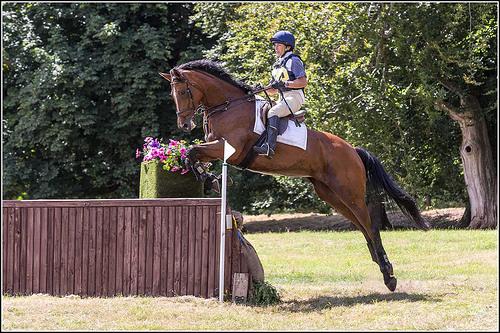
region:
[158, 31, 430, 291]
An equestrian jumping over an obstacle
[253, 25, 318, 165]
An equestrian on horseback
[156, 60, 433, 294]
A horse jumping over a wooden wall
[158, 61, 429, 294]
A horse jumping over an obstacle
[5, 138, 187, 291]
Flowers on a wooden fence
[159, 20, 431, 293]
Horseback rider jumping a wall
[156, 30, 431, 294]
A horse jumping over a wall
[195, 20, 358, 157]
Horseback rider on a horse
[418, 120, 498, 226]
A tree trunk with a hole in it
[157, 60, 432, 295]
Horse and rider obstacle course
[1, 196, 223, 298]
brown wood barrier fence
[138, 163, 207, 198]
green basket for flowers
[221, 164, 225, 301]
white metal mini flag pole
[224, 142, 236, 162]
white triangle mini flag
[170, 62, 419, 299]
brown and black horse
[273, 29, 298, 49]
blue plastic riding helmet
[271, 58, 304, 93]
blue and yellow shirt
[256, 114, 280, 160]
black leather riding boots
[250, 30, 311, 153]
woman riding on horse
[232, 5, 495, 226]
tree with green leaves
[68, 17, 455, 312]
A horses is jumping over something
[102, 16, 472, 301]
Someone is riding a horse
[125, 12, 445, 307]
A horse is moving quickly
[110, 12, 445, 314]
Someone is training their horse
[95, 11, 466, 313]
The horse is wearing a saddle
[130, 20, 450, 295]
A person is wearing a helmet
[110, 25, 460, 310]
A horse is jumping very high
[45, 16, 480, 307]
A horses is jumping on somebody's property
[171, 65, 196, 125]
The head of a horse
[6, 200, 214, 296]
A wooden fence on somebody's property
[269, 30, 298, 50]
A blue helmet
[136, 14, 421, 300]
An equestrian rider in competition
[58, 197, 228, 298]
A wooden equestrian fence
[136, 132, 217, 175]
Colorful flowers in a green planter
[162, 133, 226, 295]
A horse's front hoofs over the barrier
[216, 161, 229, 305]
A white fence pole support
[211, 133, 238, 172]
A white flag topping the pole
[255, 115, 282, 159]
Black riding boots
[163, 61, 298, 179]
A brown horse with black mane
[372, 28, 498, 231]
A tree in the background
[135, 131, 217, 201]
a box of flowers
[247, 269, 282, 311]
weeds by the ground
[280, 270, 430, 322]
a shadow of a horse on the ground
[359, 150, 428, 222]
a black tail on a horse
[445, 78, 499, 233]
a brown tree trunk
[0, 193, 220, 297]
a wooden fence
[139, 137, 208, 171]
pink and purple flowers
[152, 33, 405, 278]
person riding a dark brown horse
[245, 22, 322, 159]
a jockey on a horse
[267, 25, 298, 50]
a blue helmet